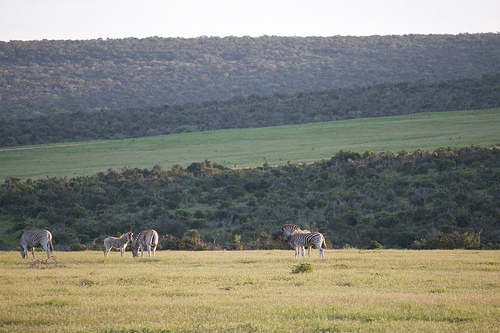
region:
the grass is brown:
[118, 268, 393, 316]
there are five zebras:
[50, 215, 340, 282]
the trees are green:
[140, 172, 490, 229]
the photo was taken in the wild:
[4, 115, 483, 327]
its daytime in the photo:
[2, 30, 496, 322]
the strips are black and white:
[38, 219, 328, 262]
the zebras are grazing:
[25, 215, 332, 275]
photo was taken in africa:
[0, 28, 497, 302]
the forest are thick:
[149, 180, 429, 222]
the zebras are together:
[20, 225, 362, 260]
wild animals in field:
[90, 210, 171, 258]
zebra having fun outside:
[270, 210, 340, 250]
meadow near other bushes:
[186, 270, 406, 325]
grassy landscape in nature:
[107, 82, 322, 198]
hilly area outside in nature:
[292, 85, 458, 180]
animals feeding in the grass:
[12, 216, 169, 271]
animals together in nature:
[15, 212, 356, 278]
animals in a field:
[10, 206, 335, 271]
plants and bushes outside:
[376, 175, 472, 235]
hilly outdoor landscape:
[3, 31, 54, 126]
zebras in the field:
[28, 206, 373, 268]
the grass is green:
[81, 142, 416, 173]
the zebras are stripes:
[258, 203, 338, 284]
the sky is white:
[146, 12, 330, 62]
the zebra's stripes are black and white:
[288, 227, 351, 276]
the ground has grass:
[151, 250, 325, 320]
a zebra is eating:
[124, 228, 185, 277]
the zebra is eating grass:
[13, 225, 75, 295]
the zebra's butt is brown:
[112, 222, 189, 275]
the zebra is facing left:
[85, 220, 139, 256]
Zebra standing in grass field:
[273, 220, 333, 260]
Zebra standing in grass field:
[92, 230, 132, 255]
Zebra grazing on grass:
[126, 226, 158, 256]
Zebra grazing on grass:
[12, 226, 52, 257]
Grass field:
[0, 246, 496, 329]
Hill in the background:
[0, 35, 495, 107]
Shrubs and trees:
[0, 162, 496, 247]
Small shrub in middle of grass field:
[285, 255, 311, 270]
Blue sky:
[0, 0, 495, 36]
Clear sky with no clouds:
[0, 1, 498, 36]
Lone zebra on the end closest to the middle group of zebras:
[12, 225, 63, 267]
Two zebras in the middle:
[102, 204, 175, 276]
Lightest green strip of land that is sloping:
[5, 109, 499, 179]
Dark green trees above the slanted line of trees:
[1, 35, 496, 109]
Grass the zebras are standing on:
[10, 247, 498, 331]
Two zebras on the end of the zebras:
[261, 203, 354, 298]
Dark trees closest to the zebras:
[2, 150, 492, 254]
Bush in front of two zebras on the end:
[277, 255, 344, 281]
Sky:
[1, 2, 496, 32]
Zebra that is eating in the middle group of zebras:
[129, 227, 175, 261]